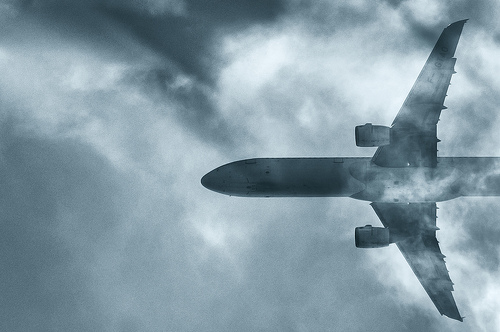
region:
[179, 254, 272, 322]
the sky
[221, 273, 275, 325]
the sky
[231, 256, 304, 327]
the sky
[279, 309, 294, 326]
the sky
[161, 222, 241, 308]
the sky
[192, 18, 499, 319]
plane in the sky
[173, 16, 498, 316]
plane flying in the clouds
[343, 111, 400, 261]
two small jet engines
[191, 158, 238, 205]
nose of the plane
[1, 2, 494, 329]
sky covered in dark gray clouds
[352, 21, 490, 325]
two airplane wings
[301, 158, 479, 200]
underbelly of the plane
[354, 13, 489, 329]
wings slightly angled back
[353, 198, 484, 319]
jet engine under the wing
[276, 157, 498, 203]
long body of the plane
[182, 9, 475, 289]
an airplane in the sky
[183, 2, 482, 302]
an airplane in the air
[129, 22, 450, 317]
a plane in the sky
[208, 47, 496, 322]
a plane in the air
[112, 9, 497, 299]
a plane in the clouds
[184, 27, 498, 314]
an airplane in the clouds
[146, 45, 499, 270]
a large plane in the air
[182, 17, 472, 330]
a large airplane in the air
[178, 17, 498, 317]
a large plane in the sky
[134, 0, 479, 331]
a large airplane in the sky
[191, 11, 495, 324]
commercial plane in sky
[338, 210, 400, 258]
engine on side of plane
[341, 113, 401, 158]
engine on side of plane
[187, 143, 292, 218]
point of nose of plane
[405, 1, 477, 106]
one wing of plane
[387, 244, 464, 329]
one wing of plane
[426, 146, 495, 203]
middle body of plane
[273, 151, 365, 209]
front of dark plane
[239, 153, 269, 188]
cock pit of plane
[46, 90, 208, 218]
dark clouds in sky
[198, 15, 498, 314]
airplane flying in the sky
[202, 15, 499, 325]
airplane between a bunch of clouds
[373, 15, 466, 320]
two wings of an airplane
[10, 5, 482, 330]
grey and cloudy sky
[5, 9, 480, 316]
bunch of grey clouds in the sky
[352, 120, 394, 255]
two lights of a airplane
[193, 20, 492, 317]
commercial airplane in the sky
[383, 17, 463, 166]
left wing of an airplane flying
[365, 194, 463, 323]
right wing of an airplane flying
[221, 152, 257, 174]
pilothouse of a commercial airplane